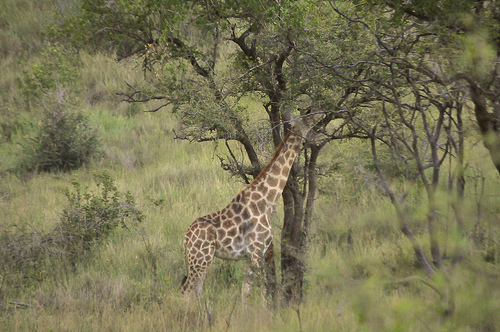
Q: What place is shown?
A: It is a field.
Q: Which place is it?
A: It is a field.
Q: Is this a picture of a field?
A: Yes, it is showing a field.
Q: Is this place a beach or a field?
A: It is a field.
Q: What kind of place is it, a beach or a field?
A: It is a field.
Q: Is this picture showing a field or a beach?
A: It is showing a field.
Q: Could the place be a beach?
A: No, it is a field.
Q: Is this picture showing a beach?
A: No, the picture is showing a field.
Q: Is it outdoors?
A: Yes, it is outdoors.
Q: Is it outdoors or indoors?
A: It is outdoors.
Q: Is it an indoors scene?
A: No, it is outdoors.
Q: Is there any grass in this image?
A: Yes, there is grass.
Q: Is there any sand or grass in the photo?
A: Yes, there is grass.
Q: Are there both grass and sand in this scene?
A: No, there is grass but no sand.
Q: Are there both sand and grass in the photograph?
A: No, there is grass but no sand.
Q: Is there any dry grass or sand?
A: Yes, there is dry grass.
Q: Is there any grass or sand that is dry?
A: Yes, the grass is dry.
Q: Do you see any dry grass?
A: Yes, there is dry grass.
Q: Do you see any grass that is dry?
A: Yes, there is grass that is dry.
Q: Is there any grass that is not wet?
A: Yes, there is dry grass.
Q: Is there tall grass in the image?
A: Yes, there is tall grass.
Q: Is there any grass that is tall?
A: Yes, there is grass that is tall.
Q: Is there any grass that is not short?
A: Yes, there is tall grass.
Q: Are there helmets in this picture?
A: No, there are no helmets.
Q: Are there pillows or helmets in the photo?
A: No, there are no helmets or pillows.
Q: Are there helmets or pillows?
A: No, there are no helmets or pillows.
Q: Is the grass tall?
A: Yes, the grass is tall.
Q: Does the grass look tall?
A: Yes, the grass is tall.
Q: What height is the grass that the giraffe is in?
A: The grass is tall.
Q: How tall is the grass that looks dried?
A: The grass is tall.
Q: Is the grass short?
A: No, the grass is tall.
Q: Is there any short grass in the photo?
A: No, there is grass but it is tall.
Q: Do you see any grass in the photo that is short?
A: No, there is grass but it is tall.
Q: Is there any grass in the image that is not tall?
A: No, there is grass but it is tall.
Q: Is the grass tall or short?
A: The grass is tall.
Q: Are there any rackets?
A: No, there are no rackets.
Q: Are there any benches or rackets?
A: No, there are no rackets or benches.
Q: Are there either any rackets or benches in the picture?
A: No, there are no rackets or benches.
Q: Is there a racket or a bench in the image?
A: No, there are no rackets or benches.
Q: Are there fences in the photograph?
A: No, there are no fences.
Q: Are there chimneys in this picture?
A: No, there are no chimneys.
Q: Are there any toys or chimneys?
A: No, there are no chimneys or toys.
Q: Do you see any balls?
A: No, there are no balls.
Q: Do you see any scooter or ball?
A: No, there are no balls or scooters.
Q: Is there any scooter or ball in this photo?
A: No, there are no balls or scooters.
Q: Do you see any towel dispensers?
A: No, there are no towel dispensers.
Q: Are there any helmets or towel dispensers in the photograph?
A: No, there are no towel dispensers or helmets.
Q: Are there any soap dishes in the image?
A: No, there are no soap dishes.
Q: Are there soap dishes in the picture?
A: No, there are no soap dishes.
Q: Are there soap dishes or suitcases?
A: No, there are no soap dishes or suitcases.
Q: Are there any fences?
A: No, there are no fences.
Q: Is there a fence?
A: No, there are no fences.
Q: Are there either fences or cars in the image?
A: No, there are no fences or cars.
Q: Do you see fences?
A: No, there are no fences.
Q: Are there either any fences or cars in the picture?
A: No, there are no fences or cars.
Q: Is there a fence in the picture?
A: No, there are no fences.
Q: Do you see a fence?
A: No, there are no fences.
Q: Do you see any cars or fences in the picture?
A: No, there are no fences or cars.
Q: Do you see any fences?
A: No, there are no fences.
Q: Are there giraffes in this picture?
A: Yes, there is a giraffe.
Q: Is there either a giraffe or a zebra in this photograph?
A: Yes, there is a giraffe.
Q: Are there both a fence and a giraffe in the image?
A: No, there is a giraffe but no fences.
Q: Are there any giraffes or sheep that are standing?
A: Yes, the giraffe is standing.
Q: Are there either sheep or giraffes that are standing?
A: Yes, the giraffe is standing.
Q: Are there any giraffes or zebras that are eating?
A: Yes, the giraffe is eating.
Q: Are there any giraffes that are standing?
A: Yes, there is a giraffe that is standing.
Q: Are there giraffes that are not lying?
A: Yes, there is a giraffe that is standing.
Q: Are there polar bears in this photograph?
A: No, there are no polar bears.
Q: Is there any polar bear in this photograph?
A: No, there are no polar bears.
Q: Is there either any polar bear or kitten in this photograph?
A: No, there are no polar bears or kittens.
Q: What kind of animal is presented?
A: The animal is a giraffe.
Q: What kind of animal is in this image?
A: The animal is a giraffe.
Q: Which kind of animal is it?
A: The animal is a giraffe.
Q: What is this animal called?
A: This is a giraffe.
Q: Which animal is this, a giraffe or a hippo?
A: This is a giraffe.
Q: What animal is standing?
A: The animal is a giraffe.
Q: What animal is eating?
A: The animal is a giraffe.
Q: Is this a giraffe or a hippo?
A: This is a giraffe.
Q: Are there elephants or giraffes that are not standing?
A: No, there is a giraffe but it is standing.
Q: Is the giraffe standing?
A: Yes, the giraffe is standing.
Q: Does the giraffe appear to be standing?
A: Yes, the giraffe is standing.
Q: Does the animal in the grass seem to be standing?
A: Yes, the giraffe is standing.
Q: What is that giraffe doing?
A: The giraffe is standing.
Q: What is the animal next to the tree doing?
A: The giraffe is standing.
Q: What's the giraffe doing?
A: The giraffe is standing.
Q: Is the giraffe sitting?
A: No, the giraffe is standing.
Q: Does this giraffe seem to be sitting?
A: No, the giraffe is standing.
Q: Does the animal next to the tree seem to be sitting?
A: No, the giraffe is standing.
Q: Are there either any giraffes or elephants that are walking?
A: No, there is a giraffe but it is standing.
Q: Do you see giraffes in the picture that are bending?
A: No, there is a giraffe but it is standing.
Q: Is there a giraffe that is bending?
A: No, there is a giraffe but it is standing.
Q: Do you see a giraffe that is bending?
A: No, there is a giraffe but it is standing.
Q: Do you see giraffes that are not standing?
A: No, there is a giraffe but it is standing.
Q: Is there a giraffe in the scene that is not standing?
A: No, there is a giraffe but it is standing.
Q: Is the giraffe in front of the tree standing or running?
A: The giraffe is standing.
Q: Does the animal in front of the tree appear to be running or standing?
A: The giraffe is standing.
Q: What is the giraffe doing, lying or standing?
A: The giraffe is standing.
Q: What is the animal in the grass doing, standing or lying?
A: The giraffe is standing.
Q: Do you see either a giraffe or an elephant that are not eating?
A: No, there is a giraffe but it is eating.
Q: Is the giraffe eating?
A: Yes, the giraffe is eating.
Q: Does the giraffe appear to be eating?
A: Yes, the giraffe is eating.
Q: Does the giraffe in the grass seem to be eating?
A: Yes, the giraffe is eating.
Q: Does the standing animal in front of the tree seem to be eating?
A: Yes, the giraffe is eating.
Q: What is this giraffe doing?
A: The giraffe is eating.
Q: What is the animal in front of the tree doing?
A: The giraffe is eating.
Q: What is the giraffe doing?
A: The giraffe is eating.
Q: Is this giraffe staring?
A: No, the giraffe is eating.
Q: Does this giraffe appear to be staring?
A: No, the giraffe is eating.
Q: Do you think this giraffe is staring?
A: No, the giraffe is eating.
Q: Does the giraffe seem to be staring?
A: No, the giraffe is eating.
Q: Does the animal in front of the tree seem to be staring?
A: No, the giraffe is eating.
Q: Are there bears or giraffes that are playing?
A: No, there is a giraffe but it is eating.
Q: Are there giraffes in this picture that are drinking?
A: No, there is a giraffe but it is eating.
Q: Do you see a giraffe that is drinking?
A: No, there is a giraffe but it is eating.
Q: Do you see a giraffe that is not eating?
A: No, there is a giraffe but it is eating.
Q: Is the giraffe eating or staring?
A: The giraffe is eating.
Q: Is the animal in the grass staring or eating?
A: The giraffe is eating.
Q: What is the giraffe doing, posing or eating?
A: The giraffe is eating.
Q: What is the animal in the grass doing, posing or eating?
A: The giraffe is eating.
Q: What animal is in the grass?
A: The giraffe is in the grass.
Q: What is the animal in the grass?
A: The animal is a giraffe.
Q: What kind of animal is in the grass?
A: The animal is a giraffe.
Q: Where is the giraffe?
A: The giraffe is in the grass.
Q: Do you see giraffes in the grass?
A: Yes, there is a giraffe in the grass.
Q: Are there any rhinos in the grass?
A: No, there is a giraffe in the grass.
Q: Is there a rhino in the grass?
A: No, there is a giraffe in the grass.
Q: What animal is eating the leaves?
A: The giraffe is eating the leaves.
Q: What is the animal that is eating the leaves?
A: The animal is a giraffe.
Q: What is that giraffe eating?
A: The giraffe is eating leaves.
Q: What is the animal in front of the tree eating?
A: The giraffe is eating leaves.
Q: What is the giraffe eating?
A: The giraffe is eating leaves.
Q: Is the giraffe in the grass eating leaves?
A: Yes, the giraffe is eating leaves.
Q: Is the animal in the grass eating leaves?
A: Yes, the giraffe is eating leaves.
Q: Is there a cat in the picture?
A: No, there are no cats.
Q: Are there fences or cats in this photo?
A: No, there are no cats or fences.